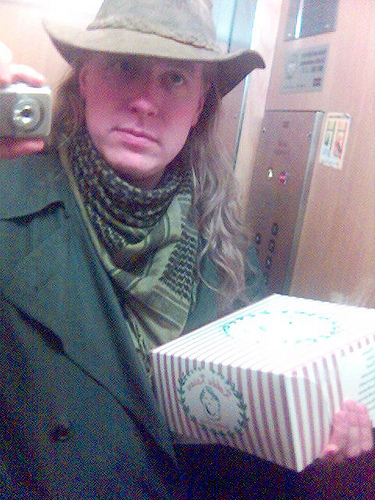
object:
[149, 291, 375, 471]
box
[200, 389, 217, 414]
person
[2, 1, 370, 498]
man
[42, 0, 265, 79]
hat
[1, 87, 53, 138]
camera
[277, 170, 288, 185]
button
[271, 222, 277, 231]
button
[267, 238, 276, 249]
button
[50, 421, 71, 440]
button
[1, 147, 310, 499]
jacket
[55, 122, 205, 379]
scarf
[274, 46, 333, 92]
plaque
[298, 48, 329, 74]
writing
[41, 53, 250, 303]
hair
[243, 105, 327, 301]
panel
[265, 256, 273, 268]
buttons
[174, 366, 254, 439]
emblem